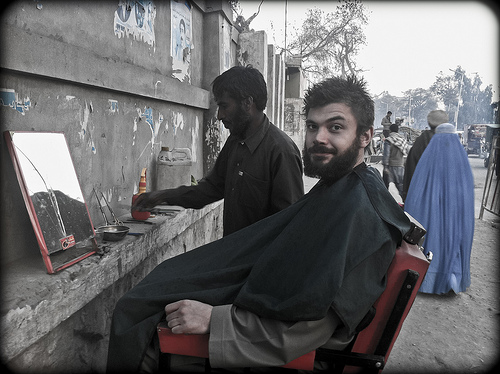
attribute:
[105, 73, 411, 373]
man — getting haircut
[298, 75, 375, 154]
hair — dark, spiked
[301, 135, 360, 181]
beard — black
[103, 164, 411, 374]
cape — black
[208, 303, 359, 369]
shirt — grey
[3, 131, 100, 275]
mirror — broken, cracked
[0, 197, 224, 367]
shelf — stone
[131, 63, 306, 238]
man — standing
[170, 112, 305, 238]
shirt — black, dark, long sleeve, collared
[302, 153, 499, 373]
street — light grey, concrete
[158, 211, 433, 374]
chair — red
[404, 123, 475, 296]
woman — wearing blue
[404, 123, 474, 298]
headscarf — blue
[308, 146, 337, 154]
mustache — black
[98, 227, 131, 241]
wash bowl — metal, silver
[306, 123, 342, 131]
eyes — brown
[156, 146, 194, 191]
storage jug — gray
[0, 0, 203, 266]
wall — gray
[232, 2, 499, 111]
sky — cloudy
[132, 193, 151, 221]
cup — red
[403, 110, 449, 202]
man — walking